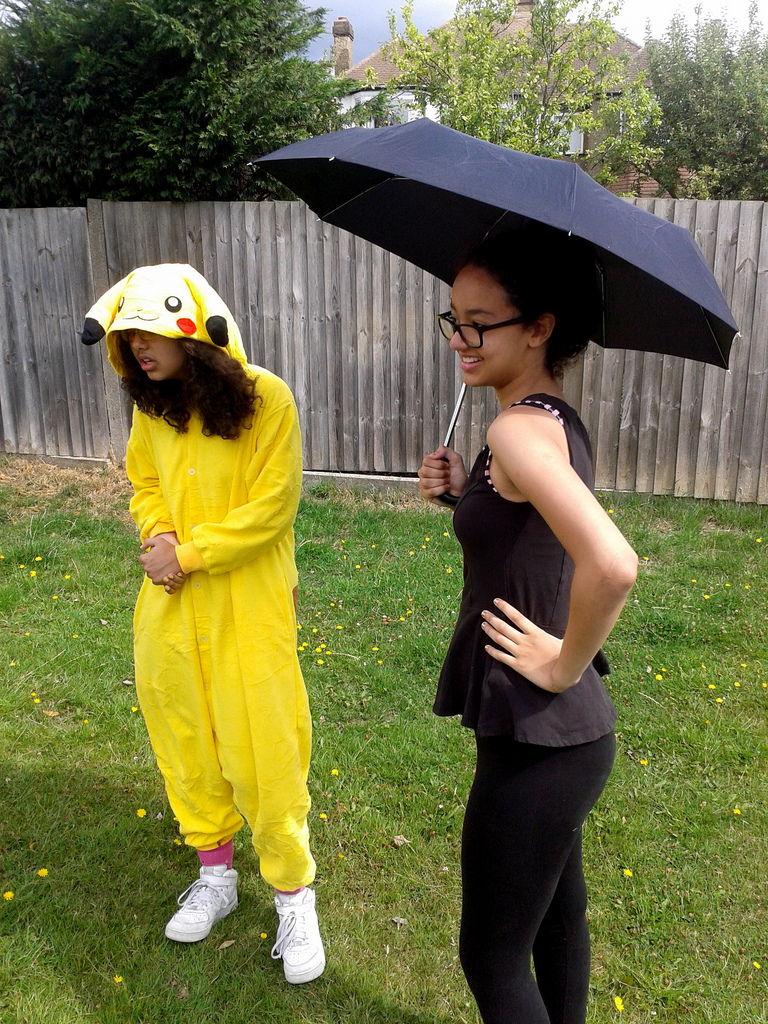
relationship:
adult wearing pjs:
[68, 258, 345, 997] [69, 255, 327, 904]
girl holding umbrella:
[409, 239, 660, 1023] [238, 107, 754, 385]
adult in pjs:
[68, 258, 345, 997] [69, 255, 327, 904]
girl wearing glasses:
[409, 239, 660, 1023] [436, 305, 536, 346]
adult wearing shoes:
[68, 258, 345, 997] [266, 891, 339, 991]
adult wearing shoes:
[68, 258, 345, 997] [159, 867, 249, 944]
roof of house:
[318, 6, 696, 94] [306, 3, 723, 198]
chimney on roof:
[320, 15, 365, 74] [318, 6, 696, 94]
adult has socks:
[68, 258, 345, 997] [183, 839, 239, 877]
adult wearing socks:
[68, 258, 345, 997] [267, 880, 323, 901]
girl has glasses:
[409, 239, 660, 1023] [436, 305, 536, 346]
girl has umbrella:
[409, 239, 660, 1023] [238, 107, 754, 385]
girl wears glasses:
[409, 239, 660, 1023] [436, 305, 536, 346]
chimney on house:
[320, 15, 365, 74] [306, 3, 723, 198]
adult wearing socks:
[68, 258, 345, 997] [183, 839, 239, 877]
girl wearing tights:
[409, 239, 660, 1023] [444, 711, 622, 1023]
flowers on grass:
[127, 806, 149, 826] [2, 457, 768, 1023]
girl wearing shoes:
[409, 239, 660, 1023] [159, 867, 249, 944]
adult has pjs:
[68, 258, 345, 997] [69, 255, 327, 904]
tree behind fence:
[2, 1, 373, 217] [2, 178, 768, 511]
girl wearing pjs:
[409, 239, 660, 1023] [69, 255, 327, 904]